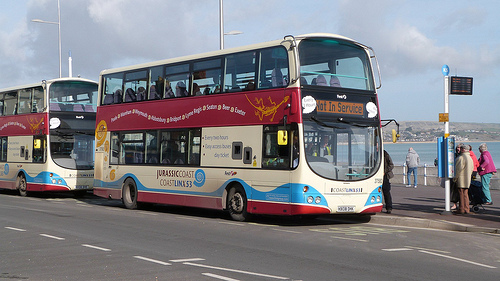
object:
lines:
[0, 220, 281, 281]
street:
[0, 190, 499, 280]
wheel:
[226, 181, 249, 220]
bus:
[95, 33, 387, 223]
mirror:
[275, 129, 289, 147]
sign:
[437, 135, 459, 180]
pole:
[442, 65, 450, 210]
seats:
[101, 84, 159, 106]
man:
[452, 144, 475, 213]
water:
[376, 138, 499, 173]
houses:
[405, 127, 469, 143]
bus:
[0, 76, 97, 196]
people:
[451, 145, 472, 215]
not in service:
[314, 100, 364, 115]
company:
[159, 178, 193, 189]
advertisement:
[96, 87, 298, 131]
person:
[404, 147, 418, 188]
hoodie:
[405, 147, 421, 169]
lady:
[473, 143, 496, 205]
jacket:
[477, 151, 498, 175]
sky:
[0, 1, 500, 123]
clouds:
[357, 7, 465, 70]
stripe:
[87, 187, 326, 218]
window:
[159, 130, 196, 163]